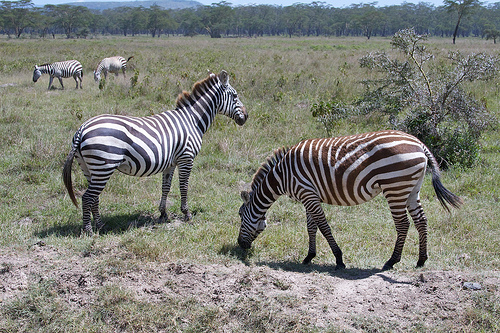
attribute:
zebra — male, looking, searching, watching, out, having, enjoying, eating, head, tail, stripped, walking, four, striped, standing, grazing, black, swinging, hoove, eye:
[38, 44, 256, 240]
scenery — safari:
[6, 28, 462, 301]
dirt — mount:
[334, 31, 442, 107]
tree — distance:
[197, 6, 279, 35]